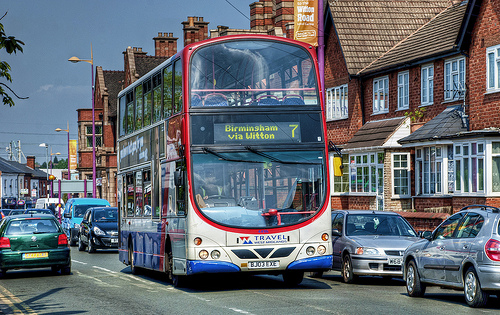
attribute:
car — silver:
[332, 208, 417, 280]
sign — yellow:
[215, 122, 302, 142]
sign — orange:
[291, 1, 324, 53]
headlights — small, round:
[195, 244, 332, 259]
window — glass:
[189, 39, 313, 109]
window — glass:
[141, 74, 158, 129]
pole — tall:
[65, 34, 113, 238]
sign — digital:
[212, 121, 301, 141]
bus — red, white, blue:
[159, 54, 371, 289]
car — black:
[76, 204, 121, 262]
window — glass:
[133, 85, 143, 128]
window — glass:
[113, 96, 127, 142]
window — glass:
[192, 46, 322, 108]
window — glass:
[162, 59, 173, 119]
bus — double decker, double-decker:
[115, 36, 333, 287]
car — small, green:
[0, 213, 71, 274]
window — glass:
[171, 56, 184, 113]